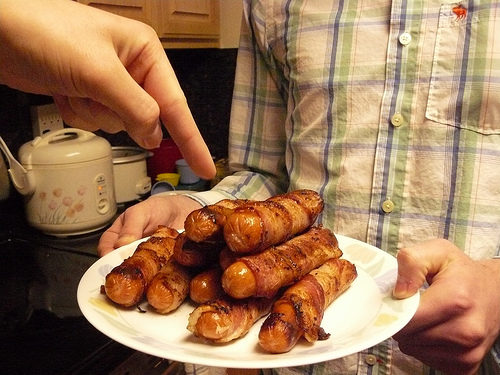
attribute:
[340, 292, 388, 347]
plate — round, circular, white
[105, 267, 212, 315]
hot dogs — 10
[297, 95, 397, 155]
shirt — white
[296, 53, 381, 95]
stripes — vertical, blue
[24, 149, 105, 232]
crock pot — white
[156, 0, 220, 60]
cabinet — wooden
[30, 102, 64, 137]
outlet — white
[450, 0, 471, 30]
emblem — orange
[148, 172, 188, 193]
cup — yellow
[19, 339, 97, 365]
counter — black